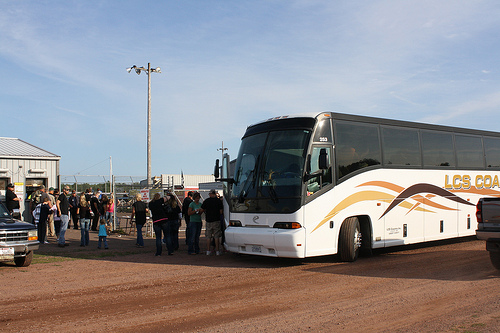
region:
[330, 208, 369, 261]
Front tire of bus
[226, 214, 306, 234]
Front head lights of bus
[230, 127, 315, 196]
Front windshield of bus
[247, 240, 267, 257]
License plate on bus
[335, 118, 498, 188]
Side windows on bus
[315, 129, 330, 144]
Number on the bus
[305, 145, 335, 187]
Side mirror on bus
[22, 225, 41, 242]
Front headlight of vehicle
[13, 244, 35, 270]
Front tire of vehicle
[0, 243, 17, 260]
License plate of vehicle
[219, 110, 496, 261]
bus on the road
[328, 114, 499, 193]
dark windows on the side of the bus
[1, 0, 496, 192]
thin white clouds in the pale blue sky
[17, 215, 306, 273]
shadow on the ground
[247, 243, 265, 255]
license plate on the front of the bus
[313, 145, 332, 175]
mirror on the side of the bus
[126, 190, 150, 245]
person walking on the dirt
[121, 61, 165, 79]
lights on the top of the pole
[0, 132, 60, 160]
roof of the building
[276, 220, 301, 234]
left headlight on bus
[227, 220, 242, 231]
right headlight on bus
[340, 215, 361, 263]
black tire on bus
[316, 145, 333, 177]
sideview mirror on bus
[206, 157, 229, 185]
right side view mirror on bus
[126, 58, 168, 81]
light on the pole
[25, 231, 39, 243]
headlight on the car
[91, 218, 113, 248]
little girl standing on grass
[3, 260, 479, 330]
dirt road on the ground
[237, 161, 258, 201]
black windshield wiper on window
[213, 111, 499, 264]
bus on a dirt ground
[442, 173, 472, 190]
bold tan print reading LCS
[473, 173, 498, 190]
bold tan lettering reading COA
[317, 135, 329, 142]
small white number print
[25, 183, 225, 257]
group of people on a dirt ground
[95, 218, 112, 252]
young girl wearing a blue shirt and jeans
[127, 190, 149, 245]
blonde haired woman in a black shirt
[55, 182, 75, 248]
man in a black shirt wearing a hat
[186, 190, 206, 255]
woman wearing a green shirt and jeans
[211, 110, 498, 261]
bus parked on a dirt ground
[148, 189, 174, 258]
A person is standing up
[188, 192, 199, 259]
A person is standing up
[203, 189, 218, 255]
A person is standing up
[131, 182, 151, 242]
A person is standing up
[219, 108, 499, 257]
The bus is parked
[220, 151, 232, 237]
The open door of the bus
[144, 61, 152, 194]
the post is tall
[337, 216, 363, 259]
The wheel is turned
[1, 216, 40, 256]
The hood of the green truck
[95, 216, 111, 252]
The small child in the blue shirt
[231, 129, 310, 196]
The front windshield on the front of the bus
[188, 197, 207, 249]
a person standing outside